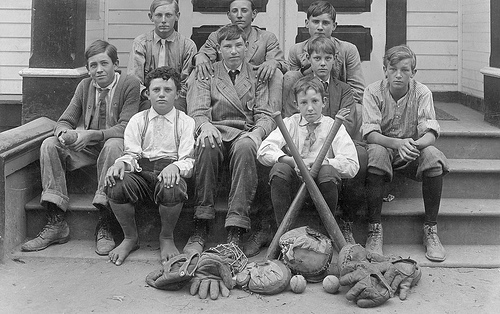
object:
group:
[21, 0, 449, 267]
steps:
[24, 117, 496, 267]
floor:
[422, 267, 497, 312]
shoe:
[422, 223, 447, 262]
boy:
[185, 32, 283, 256]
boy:
[104, 65, 196, 266]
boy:
[20, 39, 143, 256]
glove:
[338, 243, 397, 277]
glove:
[144, 251, 199, 289]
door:
[174, 0, 386, 89]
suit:
[185, 58, 281, 230]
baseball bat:
[263, 114, 346, 260]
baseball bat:
[269, 110, 348, 252]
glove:
[338, 254, 422, 307]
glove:
[380, 255, 419, 300]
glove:
[189, 253, 234, 300]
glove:
[235, 259, 291, 295]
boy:
[358, 43, 451, 261]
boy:
[254, 76, 360, 244]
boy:
[190, 0, 289, 83]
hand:
[253, 59, 278, 84]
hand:
[194, 53, 215, 80]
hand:
[157, 163, 181, 189]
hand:
[104, 161, 125, 187]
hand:
[68, 130, 92, 152]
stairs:
[447, 117, 499, 266]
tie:
[97, 89, 111, 130]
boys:
[124, 1, 197, 115]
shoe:
[364, 222, 384, 255]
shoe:
[94, 211, 120, 255]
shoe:
[21, 211, 70, 251]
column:
[1, 0, 93, 259]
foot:
[158, 232, 180, 264]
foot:
[104, 237, 139, 265]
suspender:
[174, 109, 180, 151]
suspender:
[140, 111, 148, 149]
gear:
[146, 226, 421, 308]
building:
[0, 0, 500, 272]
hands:
[194, 53, 215, 81]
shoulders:
[186, 60, 283, 98]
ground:
[9, 266, 136, 311]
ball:
[321, 275, 341, 293]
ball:
[290, 274, 306, 293]